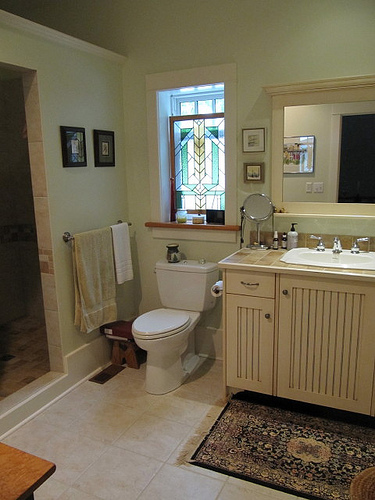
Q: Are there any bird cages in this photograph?
A: No, there are no bird cages.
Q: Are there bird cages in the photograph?
A: No, there are no bird cages.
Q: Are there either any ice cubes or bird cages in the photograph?
A: No, there are no bird cages or ice cubes.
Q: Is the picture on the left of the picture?
A: Yes, the picture is on the left of the image.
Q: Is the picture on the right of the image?
A: No, the picture is on the left of the image.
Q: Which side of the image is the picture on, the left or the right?
A: The picture is on the left of the image.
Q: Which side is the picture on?
A: The picture is on the left of the image.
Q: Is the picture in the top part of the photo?
A: Yes, the picture is in the top of the image.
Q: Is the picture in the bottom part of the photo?
A: No, the picture is in the top of the image.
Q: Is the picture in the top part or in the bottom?
A: The picture is in the top of the image.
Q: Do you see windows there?
A: Yes, there is a window.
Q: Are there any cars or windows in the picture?
A: Yes, there is a window.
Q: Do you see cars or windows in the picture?
A: Yes, there is a window.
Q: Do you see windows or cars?
A: Yes, there is a window.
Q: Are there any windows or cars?
A: Yes, there is a window.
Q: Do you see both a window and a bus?
A: No, there is a window but no buses.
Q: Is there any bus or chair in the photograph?
A: No, there are no chairs or buses.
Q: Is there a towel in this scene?
A: Yes, there is a towel.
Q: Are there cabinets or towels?
A: Yes, there is a towel.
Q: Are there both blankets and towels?
A: No, there is a towel but no blankets.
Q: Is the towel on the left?
A: Yes, the towel is on the left of the image.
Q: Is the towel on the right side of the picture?
A: No, the towel is on the left of the image.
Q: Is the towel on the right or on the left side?
A: The towel is on the left of the image.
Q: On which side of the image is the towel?
A: The towel is on the left of the image.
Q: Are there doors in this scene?
A: Yes, there is a door.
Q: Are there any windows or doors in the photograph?
A: Yes, there is a door.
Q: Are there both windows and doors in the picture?
A: Yes, there are both a door and a window.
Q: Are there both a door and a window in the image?
A: Yes, there are both a door and a window.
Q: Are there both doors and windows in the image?
A: Yes, there are both a door and a window.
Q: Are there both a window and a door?
A: Yes, there are both a door and a window.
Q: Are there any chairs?
A: No, there are no chairs.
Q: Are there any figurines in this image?
A: No, there are no figurines.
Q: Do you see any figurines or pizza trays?
A: No, there are no figurines or pizza trays.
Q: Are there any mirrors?
A: Yes, there is a mirror.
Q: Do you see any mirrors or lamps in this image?
A: Yes, there is a mirror.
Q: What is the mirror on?
A: The mirror is on the counter.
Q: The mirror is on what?
A: The mirror is on the counter.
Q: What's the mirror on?
A: The mirror is on the counter.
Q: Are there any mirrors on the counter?
A: Yes, there is a mirror on the counter.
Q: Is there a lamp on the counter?
A: No, there is a mirror on the counter.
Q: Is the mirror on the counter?
A: Yes, the mirror is on the counter.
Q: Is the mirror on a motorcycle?
A: No, the mirror is on the counter.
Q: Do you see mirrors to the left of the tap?
A: Yes, there is a mirror to the left of the tap.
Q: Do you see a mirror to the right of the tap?
A: No, the mirror is to the left of the tap.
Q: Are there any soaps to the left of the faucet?
A: No, there is a mirror to the left of the faucet.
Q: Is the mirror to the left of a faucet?
A: Yes, the mirror is to the left of a faucet.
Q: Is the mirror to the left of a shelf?
A: No, the mirror is to the left of a faucet.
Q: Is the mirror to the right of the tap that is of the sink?
A: No, the mirror is to the left of the faucet.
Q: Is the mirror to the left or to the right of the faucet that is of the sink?
A: The mirror is to the left of the tap.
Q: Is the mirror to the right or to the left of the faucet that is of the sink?
A: The mirror is to the left of the tap.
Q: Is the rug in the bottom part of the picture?
A: Yes, the rug is in the bottom of the image.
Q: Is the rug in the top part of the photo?
A: No, the rug is in the bottom of the image.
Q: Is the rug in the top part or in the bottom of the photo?
A: The rug is in the bottom of the image.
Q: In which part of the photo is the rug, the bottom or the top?
A: The rug is in the bottom of the image.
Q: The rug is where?
A: The rug is on the floor.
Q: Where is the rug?
A: The rug is on the floor.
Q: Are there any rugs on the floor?
A: Yes, there is a rug on the floor.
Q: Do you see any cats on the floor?
A: No, there is a rug on the floor.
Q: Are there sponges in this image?
A: No, there are no sponges.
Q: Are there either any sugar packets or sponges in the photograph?
A: No, there are no sponges or sugar packets.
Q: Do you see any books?
A: No, there are no books.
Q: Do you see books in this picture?
A: No, there are no books.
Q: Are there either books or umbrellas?
A: No, there are no books or umbrellas.